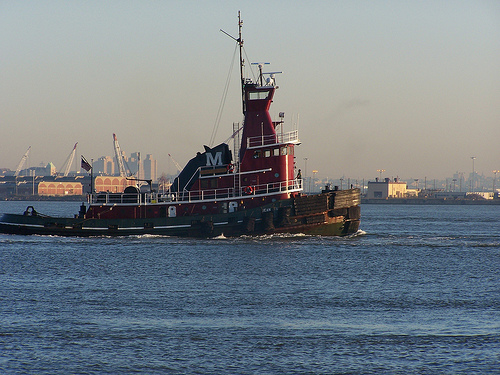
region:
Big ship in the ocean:
[6, 6, 377, 271]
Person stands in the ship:
[68, 196, 91, 226]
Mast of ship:
[231, 8, 262, 80]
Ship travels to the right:
[3, 0, 380, 250]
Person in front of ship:
[290, 164, 309, 193]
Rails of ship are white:
[85, 177, 310, 209]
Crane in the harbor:
[102, 123, 138, 176]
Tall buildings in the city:
[67, 144, 163, 183]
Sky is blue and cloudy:
[6, 4, 499, 141]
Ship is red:
[46, 36, 372, 249]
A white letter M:
[200, 149, 226, 167]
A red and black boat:
[5, 7, 373, 254]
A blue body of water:
[2, 201, 496, 373]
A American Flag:
[70, 152, 95, 177]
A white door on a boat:
[165, 206, 180, 217]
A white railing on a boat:
[248, 128, 303, 147]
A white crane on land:
[11, 138, 31, 179]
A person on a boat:
[291, 165, 302, 192]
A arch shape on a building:
[100, 175, 111, 191]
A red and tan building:
[3, 178, 83, 196]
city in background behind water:
[5, 137, 172, 192]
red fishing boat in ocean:
[6, 31, 386, 241]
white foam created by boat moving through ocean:
[116, 231, 172, 242]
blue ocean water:
[142, 261, 376, 345]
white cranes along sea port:
[14, 115, 156, 178]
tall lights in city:
[465, 146, 480, 191]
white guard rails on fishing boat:
[244, 128, 305, 156]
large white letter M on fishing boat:
[197, 145, 230, 171]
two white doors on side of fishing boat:
[157, 196, 250, 228]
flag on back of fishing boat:
[71, 149, 97, 181]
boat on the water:
[10, 11, 411, 281]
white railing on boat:
[91, 171, 311, 201]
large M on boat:
[195, 143, 225, 174]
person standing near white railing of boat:
[280, 160, 306, 195]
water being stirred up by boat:
[65, 225, 370, 250]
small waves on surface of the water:
[130, 265, 450, 372]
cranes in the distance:
[10, 115, 137, 186]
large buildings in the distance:
[75, 140, 161, 193]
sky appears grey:
[3, 1, 498, 142]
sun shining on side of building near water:
[359, 173, 422, 219]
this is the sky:
[25, 17, 179, 116]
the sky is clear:
[23, 15, 165, 113]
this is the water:
[107, 265, 394, 355]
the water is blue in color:
[163, 257, 363, 352]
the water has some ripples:
[76, 332, 383, 372]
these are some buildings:
[15, 154, 149, 191]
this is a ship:
[2, 70, 372, 237]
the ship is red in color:
[243, 110, 268, 144]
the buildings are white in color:
[136, 150, 153, 173]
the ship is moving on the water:
[13, 193, 385, 240]